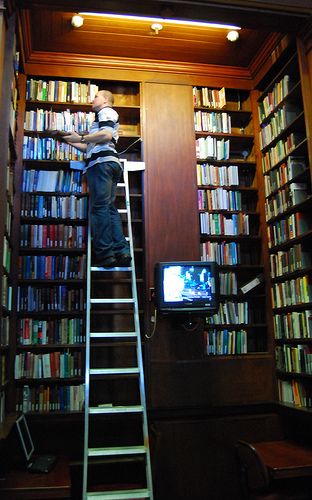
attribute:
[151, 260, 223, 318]
tv — on, black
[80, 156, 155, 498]
ladder — tall, very tall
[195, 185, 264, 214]
book shelf — wooden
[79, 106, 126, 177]
shirt — striped, stripped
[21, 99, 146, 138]
on shelf — wooden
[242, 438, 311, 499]
desk — small, brown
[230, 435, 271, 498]
desk chair — brown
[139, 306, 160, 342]
t.v. cable — white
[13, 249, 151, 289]
shelf — wooden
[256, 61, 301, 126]
shelf — wooden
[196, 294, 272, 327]
shelf — wooden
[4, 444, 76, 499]
desk — wooden, small, brown